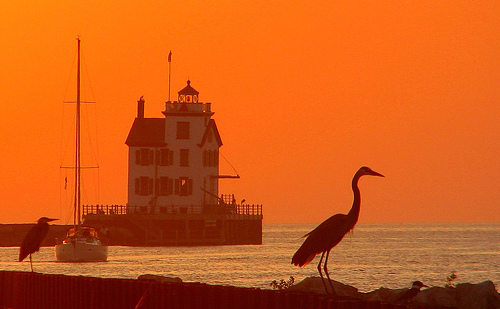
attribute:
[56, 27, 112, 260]
boat — white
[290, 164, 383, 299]
bird — Crane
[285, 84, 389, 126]
orange sky — clear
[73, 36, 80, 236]
mast — tall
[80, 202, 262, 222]
fence — large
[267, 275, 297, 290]
plants — small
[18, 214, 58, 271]
bird — smaller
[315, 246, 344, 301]
legs — thin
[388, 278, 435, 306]
bird — smaller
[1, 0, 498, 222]
sky — orange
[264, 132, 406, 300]
bird — lone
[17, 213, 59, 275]
pelican — small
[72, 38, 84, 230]
mast sails — large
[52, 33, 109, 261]
boat — white